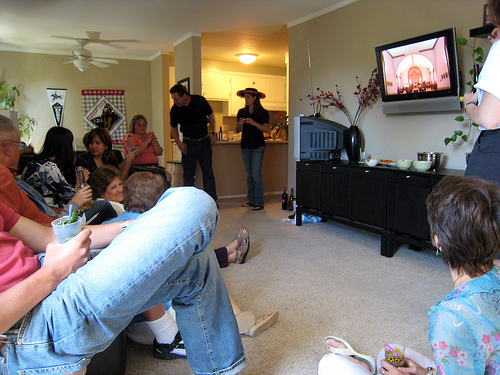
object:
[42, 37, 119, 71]
ceiling fan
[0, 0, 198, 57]
ceiling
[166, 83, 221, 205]
man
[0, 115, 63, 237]
man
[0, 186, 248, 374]
man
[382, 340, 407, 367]
cup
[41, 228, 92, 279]
hand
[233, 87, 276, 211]
friend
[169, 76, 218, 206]
friend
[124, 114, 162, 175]
friend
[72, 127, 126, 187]
friend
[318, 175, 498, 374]
friend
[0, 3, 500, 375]
living room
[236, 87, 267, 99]
hat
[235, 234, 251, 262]
sandals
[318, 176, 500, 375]
woman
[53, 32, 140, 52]
fan shadow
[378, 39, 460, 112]
entertainment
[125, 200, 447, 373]
ivory rugs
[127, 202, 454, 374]
floor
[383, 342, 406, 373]
beverage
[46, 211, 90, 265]
cup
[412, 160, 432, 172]
bowls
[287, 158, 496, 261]
counter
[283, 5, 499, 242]
wall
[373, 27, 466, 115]
television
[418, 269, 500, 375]
shirt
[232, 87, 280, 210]
woman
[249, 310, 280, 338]
sandal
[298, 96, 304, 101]
flowers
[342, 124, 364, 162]
vase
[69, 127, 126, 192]
woman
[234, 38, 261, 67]
ceiling light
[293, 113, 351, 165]
tv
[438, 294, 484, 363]
pattern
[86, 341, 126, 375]
chair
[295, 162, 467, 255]
cabinet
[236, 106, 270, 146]
shirt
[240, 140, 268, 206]
pants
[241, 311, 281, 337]
feet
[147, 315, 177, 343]
socks